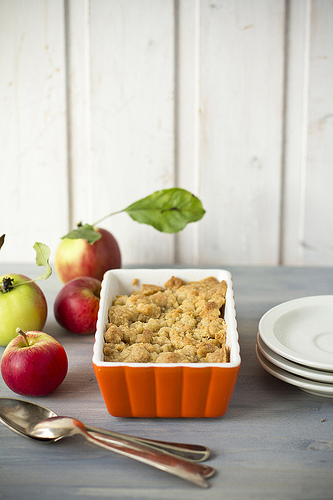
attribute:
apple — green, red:
[1, 271, 48, 345]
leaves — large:
[61, 186, 207, 246]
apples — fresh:
[0, 210, 90, 395]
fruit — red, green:
[0, 223, 121, 396]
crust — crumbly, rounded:
[103, 275, 223, 370]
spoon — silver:
[0, 385, 135, 476]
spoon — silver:
[0, 394, 220, 491]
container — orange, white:
[84, 257, 246, 444]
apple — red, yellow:
[5, 313, 87, 397]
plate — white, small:
[256, 293, 332, 374]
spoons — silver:
[0, 397, 219, 495]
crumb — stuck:
[132, 277, 140, 286]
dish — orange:
[96, 361, 234, 418]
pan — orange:
[87, 263, 243, 422]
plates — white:
[249, 289, 332, 402]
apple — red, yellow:
[54, 229, 119, 286]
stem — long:
[85, 208, 128, 224]